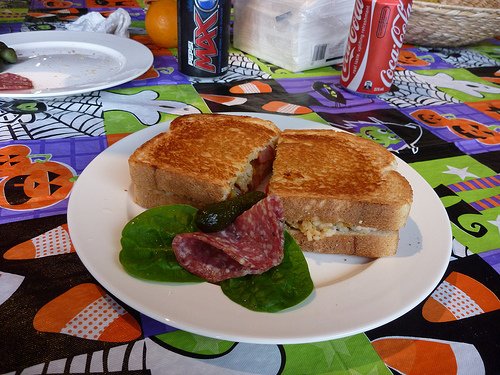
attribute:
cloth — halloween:
[1, 0, 500, 374]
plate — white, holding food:
[64, 107, 455, 347]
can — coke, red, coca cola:
[339, 1, 411, 96]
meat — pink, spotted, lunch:
[169, 199, 286, 283]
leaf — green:
[114, 194, 317, 320]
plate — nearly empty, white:
[1, 26, 156, 111]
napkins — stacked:
[230, 2, 360, 76]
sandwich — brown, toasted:
[120, 108, 415, 264]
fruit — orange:
[143, 1, 182, 50]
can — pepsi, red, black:
[174, 1, 232, 79]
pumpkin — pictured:
[411, 103, 452, 131]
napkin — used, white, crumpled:
[63, 5, 130, 42]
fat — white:
[296, 218, 353, 241]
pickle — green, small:
[195, 187, 266, 232]